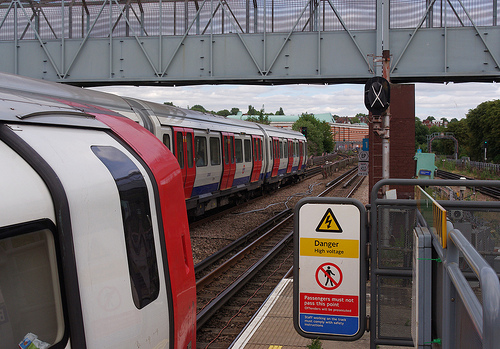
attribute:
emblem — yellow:
[289, 198, 376, 335]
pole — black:
[346, 165, 383, 347]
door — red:
[168, 124, 195, 199]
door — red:
[215, 128, 236, 190]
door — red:
[251, 136, 260, 182]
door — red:
[271, 133, 281, 177]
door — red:
[283, 135, 294, 176]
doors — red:
[220, 132, 235, 190]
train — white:
[3, 71, 367, 232]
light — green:
[479, 134, 491, 146]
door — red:
[247, 134, 264, 182]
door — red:
[268, 137, 284, 177]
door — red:
[285, 139, 295, 176]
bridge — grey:
[0, 0, 500, 85]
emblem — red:
[314, 258, 343, 288]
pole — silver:
[354, 82, 420, 267]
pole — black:
[364, 175, 389, 347]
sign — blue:
[361, 136, 371, 155]